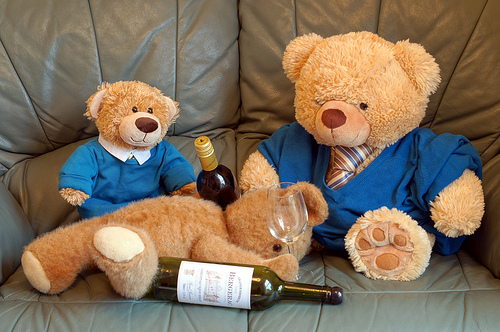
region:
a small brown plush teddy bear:
[61, 82, 201, 224]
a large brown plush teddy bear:
[243, 32, 481, 272]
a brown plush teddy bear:
[21, 184, 327, 295]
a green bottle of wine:
[154, 249, 346, 309]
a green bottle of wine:
[191, 129, 237, 201]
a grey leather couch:
[0, 1, 497, 329]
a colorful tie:
[322, 144, 376, 187]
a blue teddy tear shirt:
[58, 140, 193, 212]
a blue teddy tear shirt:
[259, 117, 486, 257]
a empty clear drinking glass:
[263, 177, 305, 259]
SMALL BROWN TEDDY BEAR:
[53, 70, 192, 208]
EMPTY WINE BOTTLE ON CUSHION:
[153, 255, 350, 311]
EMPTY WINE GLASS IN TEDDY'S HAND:
[258, 182, 319, 262]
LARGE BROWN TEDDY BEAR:
[243, 26, 484, 283]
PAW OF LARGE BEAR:
[343, 206, 438, 284]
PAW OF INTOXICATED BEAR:
[86, 224, 154, 269]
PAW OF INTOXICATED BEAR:
[11, 243, 59, 299]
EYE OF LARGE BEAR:
[353, 97, 373, 119]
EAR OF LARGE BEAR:
[393, 34, 453, 104]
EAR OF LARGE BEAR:
[276, 28, 325, 87]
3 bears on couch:
[2, 35, 478, 290]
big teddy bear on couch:
[249, 33, 486, 281]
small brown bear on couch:
[61, 67, 204, 206]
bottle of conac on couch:
[190, 131, 242, 211]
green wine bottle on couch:
[153, 250, 350, 316]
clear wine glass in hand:
[270, 179, 307, 272]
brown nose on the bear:
[135, 118, 161, 131]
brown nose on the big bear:
[320, 101, 342, 131]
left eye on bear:
[359, 98, 374, 111]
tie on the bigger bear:
[324, 144, 372, 189]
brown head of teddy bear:
[265, 26, 440, 150]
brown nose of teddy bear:
[321, 107, 348, 130]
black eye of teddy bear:
[361, 100, 366, 109]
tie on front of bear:
[320, 140, 375, 182]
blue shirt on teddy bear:
[270, 115, 465, 236]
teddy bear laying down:
[15, 183, 346, 300]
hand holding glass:
[245, 187, 320, 293]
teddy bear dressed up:
[46, 88, 185, 223]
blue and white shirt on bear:
[50, 135, 187, 227]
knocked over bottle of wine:
[163, 261, 353, 306]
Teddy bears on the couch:
[16, 24, 488, 315]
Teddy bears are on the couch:
[21, 25, 486, 305]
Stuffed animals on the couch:
[17, 25, 484, 304]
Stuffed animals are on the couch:
[15, 19, 492, 307]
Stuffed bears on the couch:
[15, 24, 480, 310]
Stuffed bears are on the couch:
[15, 22, 491, 304]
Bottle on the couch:
[135, 247, 365, 313]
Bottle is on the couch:
[147, 245, 348, 316]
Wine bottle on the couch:
[141, 252, 350, 308]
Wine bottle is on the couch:
[143, 247, 353, 319]